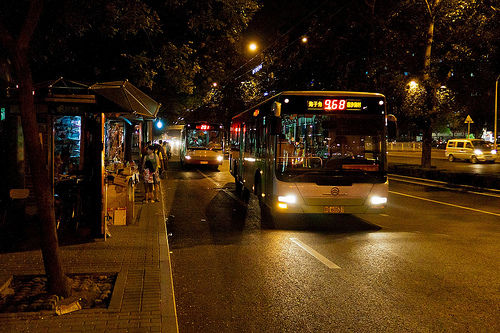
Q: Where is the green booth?
A: On the sidewalk.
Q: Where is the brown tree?
A: Next to the green booth.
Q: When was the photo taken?
A: Night time in the city.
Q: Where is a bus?
A: On the street.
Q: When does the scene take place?
A: Night.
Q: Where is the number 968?
A: On bus.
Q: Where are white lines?
A: On the street.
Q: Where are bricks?
A: On the sidewalk.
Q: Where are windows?
A: On bus.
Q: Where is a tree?
A: On the sidewalk.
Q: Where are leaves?
A: On trees.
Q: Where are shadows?
A: On the street.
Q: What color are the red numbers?
A: Red.